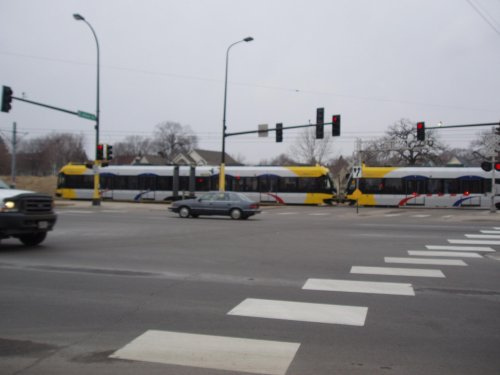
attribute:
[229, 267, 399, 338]
box — white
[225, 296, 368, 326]
line — white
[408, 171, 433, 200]
door — double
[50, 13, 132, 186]
post — light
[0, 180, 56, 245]
truck — coming up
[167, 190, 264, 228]
car — grey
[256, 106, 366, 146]
signals — red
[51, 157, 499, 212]
train — moving